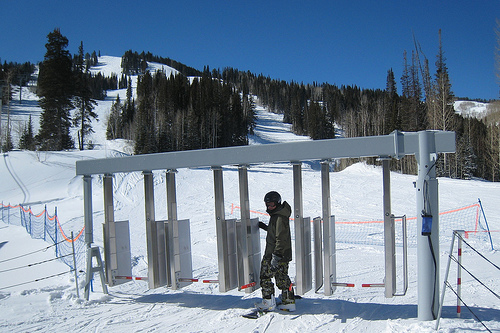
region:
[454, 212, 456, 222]
part of a fence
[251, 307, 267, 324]
part of a shoe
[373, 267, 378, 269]
part of a rail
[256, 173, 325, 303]
this is a person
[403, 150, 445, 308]
this is a pillar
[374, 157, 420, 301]
this is a pillar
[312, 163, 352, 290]
this is a pillar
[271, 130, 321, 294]
this is a pillar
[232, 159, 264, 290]
this is a pillar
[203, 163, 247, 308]
this is a pillar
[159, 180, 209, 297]
this is a pillar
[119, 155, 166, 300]
this is a pillar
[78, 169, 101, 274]
this is a pillar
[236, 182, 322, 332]
This is a person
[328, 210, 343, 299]
This is a pillar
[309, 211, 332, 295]
This is a pillar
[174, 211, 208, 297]
This is a pillar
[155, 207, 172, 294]
This is a pillar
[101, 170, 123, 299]
This is a pillar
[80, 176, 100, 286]
This is a pillar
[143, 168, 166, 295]
This is a pillar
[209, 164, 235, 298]
This is a pillar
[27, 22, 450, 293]
this is a ski slope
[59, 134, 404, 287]
these are dividers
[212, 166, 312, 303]
this is a snowboarder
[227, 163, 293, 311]
this is a person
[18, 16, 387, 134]
this is a forested area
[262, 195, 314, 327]
the man is wearing gray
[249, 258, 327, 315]
the man has camo pants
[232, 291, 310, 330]
the man's snowboard boots are white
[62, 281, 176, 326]
the snow on the ground here is white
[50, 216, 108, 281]
this is a barrier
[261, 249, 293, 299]
camoflage snow pants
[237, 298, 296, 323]
white boots on a snowboard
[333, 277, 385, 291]
red tipped flaps on a gate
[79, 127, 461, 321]
orange trimmed snow fencing